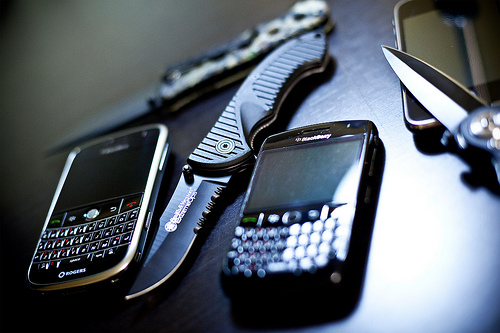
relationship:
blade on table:
[121, 37, 329, 284] [5, 3, 495, 331]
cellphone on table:
[21, 127, 175, 291] [5, 3, 495, 331]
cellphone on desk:
[217, 119, 384, 297] [81, 1, 496, 326]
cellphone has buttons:
[217, 119, 384, 297] [231, 223, 343, 279]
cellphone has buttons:
[21, 127, 175, 291] [33, 200, 145, 275]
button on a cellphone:
[62, 227, 70, 237] [21, 127, 175, 291]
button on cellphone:
[85, 206, 99, 214] [21, 127, 175, 291]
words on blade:
[167, 186, 194, 236] [121, 37, 329, 284]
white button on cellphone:
[285, 234, 297, 246] [217, 119, 384, 297]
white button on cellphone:
[306, 230, 322, 242] [217, 119, 384, 297]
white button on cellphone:
[297, 255, 314, 271] [217, 119, 384, 297]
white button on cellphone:
[86, 240, 98, 252] [21, 127, 175, 291]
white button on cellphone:
[47, 230, 57, 241] [21, 127, 175, 291]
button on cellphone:
[302, 220, 310, 234] [217, 119, 384, 297]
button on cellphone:
[323, 230, 332, 242] [217, 119, 384, 297]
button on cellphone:
[306, 245, 315, 255] [217, 119, 384, 297]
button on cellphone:
[287, 234, 294, 243] [217, 119, 384, 297]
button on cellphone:
[301, 257, 308, 266] [217, 119, 384, 297]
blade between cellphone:
[121, 37, 363, 292] [217, 119, 384, 297]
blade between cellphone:
[121, 37, 363, 292] [21, 127, 175, 291]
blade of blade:
[387, 44, 482, 112] [378, 44, 499, 138]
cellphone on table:
[217, 119, 384, 297] [5, 3, 495, 331]